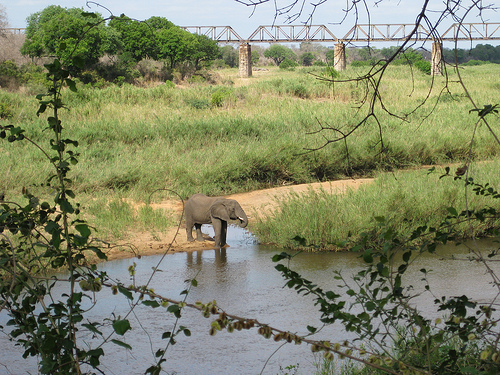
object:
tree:
[17, 5, 119, 74]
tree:
[101, 13, 152, 80]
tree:
[150, 27, 192, 77]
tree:
[261, 44, 295, 68]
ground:
[0, 43, 499, 284]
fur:
[182, 193, 249, 248]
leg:
[184, 222, 195, 242]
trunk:
[238, 212, 249, 229]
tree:
[182, 33, 224, 72]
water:
[0, 223, 499, 375]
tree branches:
[290, 0, 428, 177]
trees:
[220, 49, 239, 69]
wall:
[124, 65, 184, 137]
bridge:
[0, 23, 499, 80]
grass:
[0, 42, 499, 287]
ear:
[208, 202, 233, 226]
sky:
[0, 0, 499, 50]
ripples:
[0, 224, 498, 375]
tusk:
[236, 215, 244, 221]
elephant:
[182, 193, 248, 248]